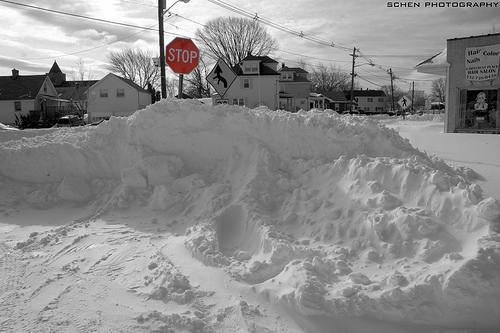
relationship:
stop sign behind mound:
[162, 37, 200, 89] [11, 88, 484, 301]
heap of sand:
[142, 72, 411, 262] [144, 124, 404, 258]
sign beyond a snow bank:
[162, 34, 202, 76] [0, 96, 498, 328]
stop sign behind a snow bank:
[162, 37, 201, 77] [0, 96, 498, 328]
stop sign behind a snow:
[162, 37, 201, 77] [0, 97, 499, 331]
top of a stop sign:
[163, 36, 197, 73] [162, 37, 201, 77]